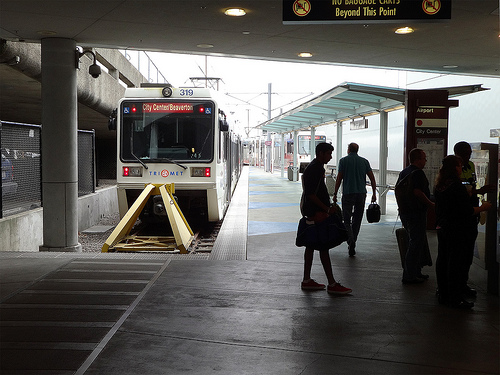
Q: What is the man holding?
A: Luggage.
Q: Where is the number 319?
A: On the front of the train.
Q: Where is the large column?
A: To the left of the train, and in front of it.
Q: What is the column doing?
A: Supporting the enclosed portion of the station.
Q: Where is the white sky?
A: Beyond the enclosed portion of the station.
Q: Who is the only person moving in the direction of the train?
A: A man with a bag in his right hand.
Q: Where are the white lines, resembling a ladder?
A: To the right of the column, on the enclosed portion of the platform.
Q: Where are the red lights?
A: On the front of the train.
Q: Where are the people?
A: At a train station.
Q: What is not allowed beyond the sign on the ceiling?
A: Baggage carts.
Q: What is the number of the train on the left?
A: 319.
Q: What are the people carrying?
A: Bags.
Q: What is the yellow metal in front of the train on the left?
A: A train stopper.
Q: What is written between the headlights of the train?
A: "TRI MET".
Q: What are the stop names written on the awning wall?
A: "Airport" and "City Center".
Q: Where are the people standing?
A: On the platform.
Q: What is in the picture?
A: A train.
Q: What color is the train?
A: White.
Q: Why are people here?
A: To travel.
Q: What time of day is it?
A: Daytime.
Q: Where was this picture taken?
A: A train station.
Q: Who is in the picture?
A: Travelers.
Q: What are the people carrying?
A: Luggage.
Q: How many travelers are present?
A: Five.